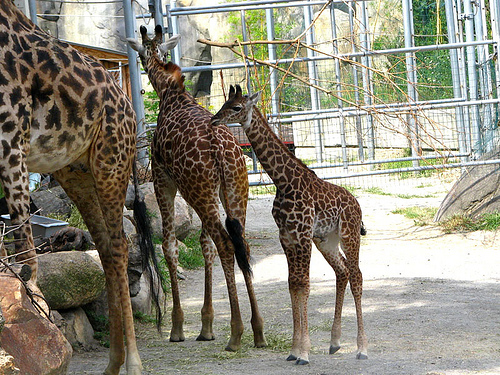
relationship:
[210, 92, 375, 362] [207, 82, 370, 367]
giraffe near or giraffe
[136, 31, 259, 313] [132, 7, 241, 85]
giraffe looking away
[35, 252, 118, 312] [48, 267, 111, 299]
rocks have moss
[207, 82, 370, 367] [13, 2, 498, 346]
giraffe in enclosure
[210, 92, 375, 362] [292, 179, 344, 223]
giraffe has spots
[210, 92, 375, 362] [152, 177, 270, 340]
giraffe has legs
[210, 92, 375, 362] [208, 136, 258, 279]
giraffe has tail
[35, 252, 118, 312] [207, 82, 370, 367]
rocks near giraffe